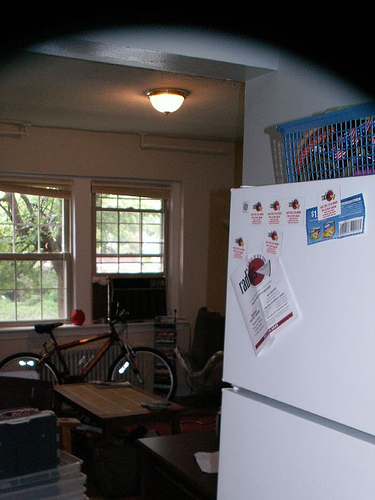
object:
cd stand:
[154, 316, 178, 398]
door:
[215, 386, 373, 500]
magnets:
[230, 189, 364, 357]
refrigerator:
[216, 174, 373, 500]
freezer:
[216, 172, 375, 500]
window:
[2, 184, 72, 322]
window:
[92, 193, 164, 276]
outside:
[96, 193, 164, 274]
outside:
[0, 189, 63, 320]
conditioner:
[92, 272, 167, 321]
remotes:
[142, 398, 172, 411]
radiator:
[41, 347, 142, 384]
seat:
[32, 317, 62, 333]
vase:
[71, 309, 85, 326]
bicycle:
[0, 299, 177, 410]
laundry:
[276, 103, 375, 185]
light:
[143, 88, 192, 116]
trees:
[0, 192, 59, 317]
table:
[51, 381, 187, 454]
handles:
[107, 303, 126, 324]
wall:
[0, 122, 239, 411]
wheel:
[0, 351, 61, 412]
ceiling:
[0, 0, 375, 140]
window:
[1, 171, 76, 331]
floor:
[1, 396, 221, 500]